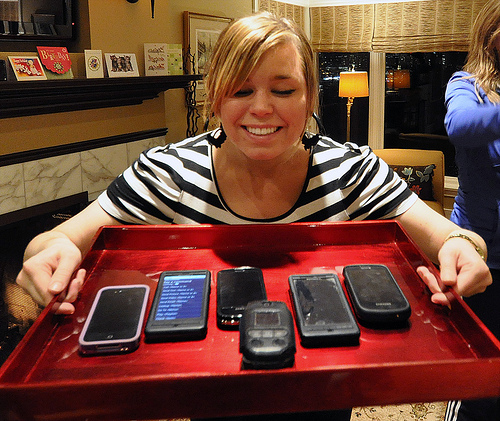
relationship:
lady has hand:
[12, 11, 499, 314] [413, 232, 496, 313]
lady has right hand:
[12, 11, 499, 314] [10, 252, 87, 310]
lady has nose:
[12, 11, 499, 314] [251, 100, 276, 123]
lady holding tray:
[12, 11, 499, 314] [2, 221, 499, 419]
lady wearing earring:
[12, 11, 499, 314] [298, 110, 327, 150]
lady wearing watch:
[12, 11, 499, 314] [445, 230, 486, 263]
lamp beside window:
[337, 68, 374, 148] [310, 6, 496, 161]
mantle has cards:
[1, 71, 201, 119] [6, 42, 184, 77]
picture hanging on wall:
[180, 10, 243, 108] [3, 3, 258, 196]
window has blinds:
[310, 6, 496, 161] [308, 3, 498, 54]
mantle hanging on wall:
[1, 71, 201, 119] [3, 3, 258, 196]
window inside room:
[310, 6, 496, 161] [1, 1, 498, 319]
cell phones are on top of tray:
[81, 261, 407, 362] [2, 221, 499, 419]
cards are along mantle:
[6, 42, 184, 77] [1, 71, 201, 119]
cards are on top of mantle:
[6, 42, 184, 77] [1, 71, 201, 119]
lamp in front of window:
[337, 68, 374, 148] [310, 6, 496, 161]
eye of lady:
[231, 82, 254, 99] [172, 0, 412, 261]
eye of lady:
[269, 82, 298, 99] [120, 0, 455, 261]